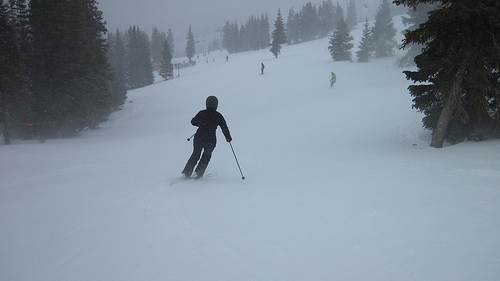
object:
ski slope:
[143, 20, 375, 241]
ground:
[9, 130, 499, 278]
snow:
[116, 65, 409, 279]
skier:
[190, 83, 248, 192]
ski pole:
[224, 134, 256, 175]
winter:
[9, 20, 498, 263]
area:
[0, 0, 490, 279]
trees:
[0, 0, 498, 120]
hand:
[224, 133, 236, 144]